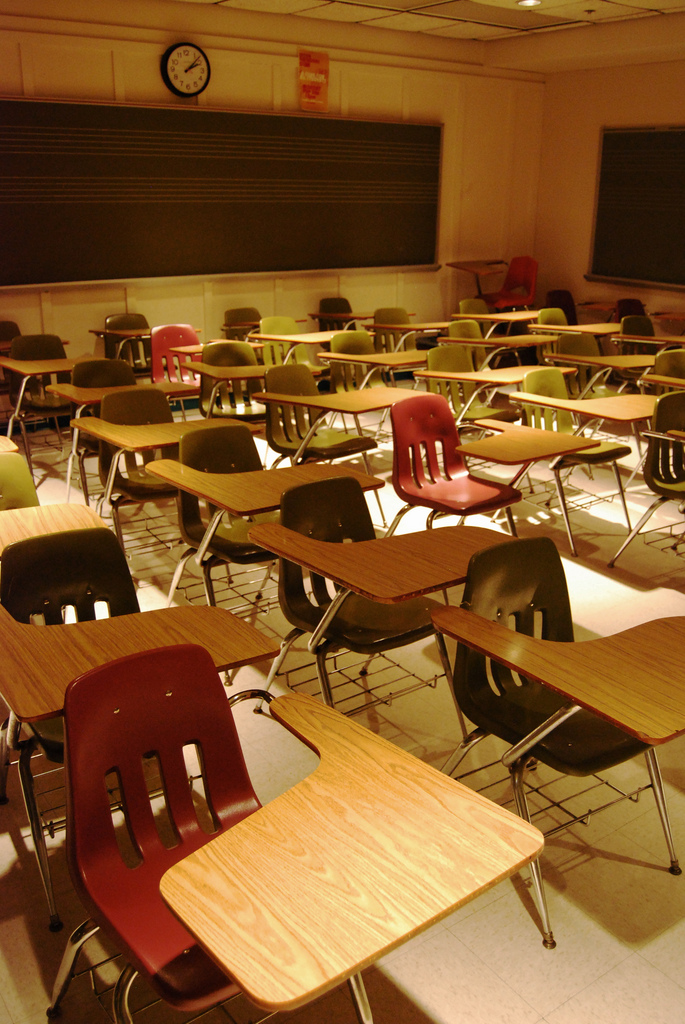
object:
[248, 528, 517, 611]
desk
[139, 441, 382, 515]
desk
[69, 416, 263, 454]
desk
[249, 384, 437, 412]
desk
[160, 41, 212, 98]
clock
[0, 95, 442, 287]
chalkboard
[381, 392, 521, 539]
chair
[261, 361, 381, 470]
chair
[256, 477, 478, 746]
chair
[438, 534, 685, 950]
chair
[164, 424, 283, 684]
chair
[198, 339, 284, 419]
chair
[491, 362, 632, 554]
chair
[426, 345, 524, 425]
chair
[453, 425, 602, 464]
desk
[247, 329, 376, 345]
desk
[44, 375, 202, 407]
desk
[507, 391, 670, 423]
desk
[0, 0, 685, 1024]
classroom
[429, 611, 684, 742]
desk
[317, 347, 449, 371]
desk